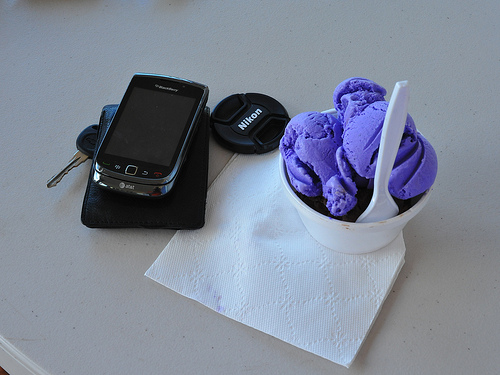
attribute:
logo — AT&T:
[113, 178, 138, 193]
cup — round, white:
[303, 107, 443, 247]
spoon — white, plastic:
[352, 75, 421, 224]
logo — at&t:
[122, 182, 137, 192]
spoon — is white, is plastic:
[356, 79, 409, 223]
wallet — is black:
[53, 83, 210, 244]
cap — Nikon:
[216, 94, 289, 154]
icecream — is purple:
[277, 71, 444, 217]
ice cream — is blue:
[278, 75, 436, 217]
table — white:
[0, 0, 500, 372]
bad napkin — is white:
[146, 142, 408, 366]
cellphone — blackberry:
[89, 73, 207, 200]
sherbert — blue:
[275, 62, 462, 242]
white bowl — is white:
[277, 115, 438, 255]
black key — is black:
[40, 113, 97, 188]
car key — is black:
[44, 119, 96, 187]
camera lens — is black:
[209, 89, 291, 161]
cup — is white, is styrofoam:
[281, 108, 434, 255]